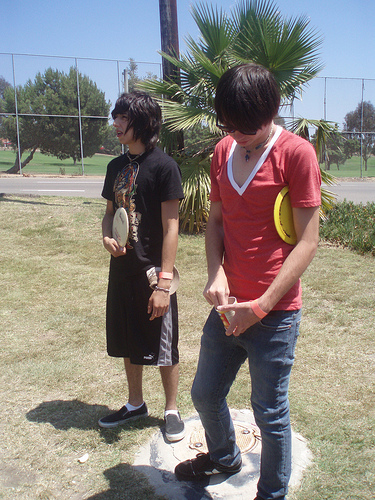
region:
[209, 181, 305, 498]
a boy in red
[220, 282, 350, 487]
a boy in red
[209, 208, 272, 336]
a boy in red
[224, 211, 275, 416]
a boy in red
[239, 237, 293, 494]
a boy in red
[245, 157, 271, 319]
a boy in red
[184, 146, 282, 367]
a boy in red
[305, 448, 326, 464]
part of a ground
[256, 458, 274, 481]
part of a jeans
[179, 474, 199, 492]
part of a floor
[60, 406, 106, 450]
edge of a shade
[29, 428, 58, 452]
part of a ground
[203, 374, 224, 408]
part of a trouser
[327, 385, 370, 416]
part of some grass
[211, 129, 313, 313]
The boy on left shirt color is red.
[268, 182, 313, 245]
The boy on the left has a yellow disc.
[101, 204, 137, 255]
Boy on right has a white disc.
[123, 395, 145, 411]
Boys socks are white.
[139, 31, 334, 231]
There is a palm tree in background.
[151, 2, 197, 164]
There is a pole in background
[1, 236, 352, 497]
The grass is dry.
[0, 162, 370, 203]
There is a road in background.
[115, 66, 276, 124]
The boys hair color is black.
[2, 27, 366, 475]
The boys are playing disc golf.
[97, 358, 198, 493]
shadows of the boy's on ground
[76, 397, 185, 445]
boys black van sneakers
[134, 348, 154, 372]
logo on boy's shorts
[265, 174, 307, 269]
yellow frisbee under boy's arm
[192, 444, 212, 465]
shoe laces on boy's shoe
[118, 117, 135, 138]
lock of hair on boy's face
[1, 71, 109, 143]
mesh fence behind the road.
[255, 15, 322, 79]
palm frond on tree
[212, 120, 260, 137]
sun glasses on boy's face.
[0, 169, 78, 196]
street behind the field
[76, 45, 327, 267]
two men are here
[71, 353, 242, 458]
he is wearing slip ons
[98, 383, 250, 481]
the shoes are black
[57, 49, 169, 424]
his shirt is black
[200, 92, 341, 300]
this man wears a red shirt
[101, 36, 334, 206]
there is a palm tree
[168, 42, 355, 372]
the shirt is vneck cut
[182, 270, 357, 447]
this man wears jeans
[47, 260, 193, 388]
this man wears shorts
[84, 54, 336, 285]
they both have dark hair